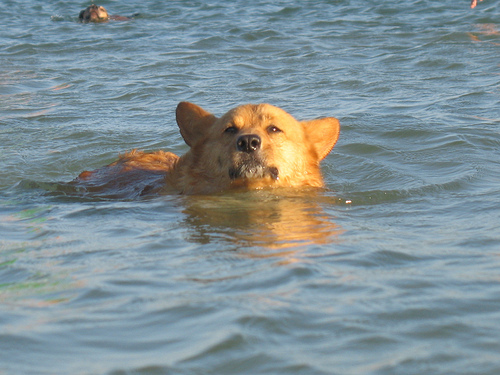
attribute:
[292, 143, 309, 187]
fur — wet  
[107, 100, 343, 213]
dog — tan 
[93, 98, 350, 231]
dog — reflection   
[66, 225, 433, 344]
water — dark  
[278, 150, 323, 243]
light — reflecting   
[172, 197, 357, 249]
surface — water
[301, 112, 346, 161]
ears — tan dog 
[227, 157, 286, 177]
mouth — brown dark dog 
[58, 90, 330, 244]
dog — brown 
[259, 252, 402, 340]
ripples — greenish blue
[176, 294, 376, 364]
water — greenish blue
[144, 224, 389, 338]
water — greenish blue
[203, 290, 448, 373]
water — greenish blue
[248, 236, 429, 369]
water — greenish blue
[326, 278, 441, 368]
water — greenish blue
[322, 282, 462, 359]
water — greenish blue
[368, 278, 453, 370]
water — greenish blue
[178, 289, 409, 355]
water — greenish blue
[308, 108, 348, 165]
ears — Brown 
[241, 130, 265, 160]
nose — Black 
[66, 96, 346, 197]
dog — light brown 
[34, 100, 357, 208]
dog — Reflection , tan 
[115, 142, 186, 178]
back — background , dog  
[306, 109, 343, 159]
ear —  dog's right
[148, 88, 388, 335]
camera — dog's left 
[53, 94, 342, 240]
dog — distant brown  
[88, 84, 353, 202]
dog — brown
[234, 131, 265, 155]
nose — black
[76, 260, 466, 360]
water — calm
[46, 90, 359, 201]
dog — tan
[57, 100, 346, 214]
dog — swimming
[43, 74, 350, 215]
dog — wet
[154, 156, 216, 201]
fur — wet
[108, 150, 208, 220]
fur — wet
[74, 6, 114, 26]
dog — brown, tan